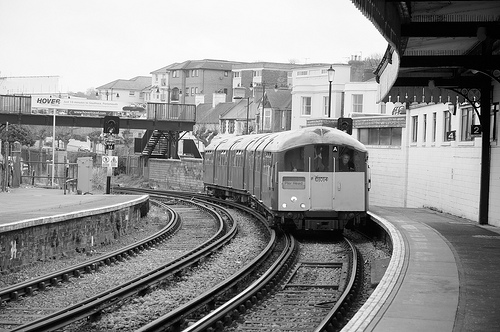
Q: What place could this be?
A: It is a station.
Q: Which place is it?
A: It is a station.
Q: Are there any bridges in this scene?
A: Yes, there is a bridge.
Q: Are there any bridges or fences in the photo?
A: Yes, there is a bridge.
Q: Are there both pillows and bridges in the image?
A: No, there is a bridge but no pillows.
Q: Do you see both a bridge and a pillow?
A: No, there is a bridge but no pillows.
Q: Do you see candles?
A: No, there are no candles.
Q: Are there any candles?
A: No, there are no candles.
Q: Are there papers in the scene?
A: No, there are no papers.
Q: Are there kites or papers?
A: No, there are no papers or kites.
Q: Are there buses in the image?
A: No, there are no buses.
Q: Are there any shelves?
A: No, there are no shelves.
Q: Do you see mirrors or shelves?
A: No, there are no shelves or mirrors.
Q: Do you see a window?
A: Yes, there is a window.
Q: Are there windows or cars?
A: Yes, there is a window.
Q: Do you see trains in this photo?
A: Yes, there is a train.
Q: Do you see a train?
A: Yes, there is a train.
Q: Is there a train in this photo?
A: Yes, there is a train.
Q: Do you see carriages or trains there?
A: Yes, there is a train.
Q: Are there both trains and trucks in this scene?
A: No, there is a train but no trucks.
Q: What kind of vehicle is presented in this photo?
A: The vehicle is a train.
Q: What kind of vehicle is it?
A: The vehicle is a train.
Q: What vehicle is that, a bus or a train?
A: That is a train.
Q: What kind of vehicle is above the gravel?
A: The vehicle is a train.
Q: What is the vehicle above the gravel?
A: The vehicle is a train.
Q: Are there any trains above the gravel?
A: Yes, there is a train above the gravel.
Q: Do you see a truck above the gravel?
A: No, there is a train above the gravel.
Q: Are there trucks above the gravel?
A: No, there is a train above the gravel.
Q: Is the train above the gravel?
A: Yes, the train is above the gravel.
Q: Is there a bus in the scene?
A: No, there are no buses.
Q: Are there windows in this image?
A: Yes, there is a window.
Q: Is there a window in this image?
A: Yes, there is a window.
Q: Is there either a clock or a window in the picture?
A: Yes, there is a window.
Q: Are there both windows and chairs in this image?
A: No, there is a window but no chairs.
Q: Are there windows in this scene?
A: Yes, there is a window.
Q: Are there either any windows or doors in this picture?
A: Yes, there is a window.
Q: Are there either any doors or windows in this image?
A: Yes, there is a window.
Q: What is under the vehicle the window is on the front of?
A: The gravel is under the train.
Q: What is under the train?
A: The gravel is under the train.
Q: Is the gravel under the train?
A: Yes, the gravel is under the train.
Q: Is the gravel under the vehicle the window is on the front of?
A: Yes, the gravel is under the train.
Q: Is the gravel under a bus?
A: No, the gravel is under the train.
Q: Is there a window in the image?
A: Yes, there is a window.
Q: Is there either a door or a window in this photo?
A: Yes, there is a window.